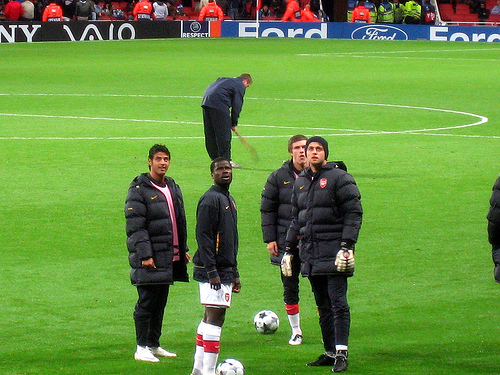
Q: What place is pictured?
A: It is a field.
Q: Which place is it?
A: It is a field.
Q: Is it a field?
A: Yes, it is a field.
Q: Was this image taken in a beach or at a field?
A: It was taken at a field.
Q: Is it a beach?
A: No, it is a field.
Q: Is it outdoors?
A: Yes, it is outdoors.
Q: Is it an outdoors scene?
A: Yes, it is outdoors.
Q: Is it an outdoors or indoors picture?
A: It is outdoors.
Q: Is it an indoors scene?
A: No, it is outdoors.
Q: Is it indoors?
A: No, it is outdoors.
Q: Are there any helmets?
A: No, there are no helmets.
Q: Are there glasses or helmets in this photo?
A: No, there are no helmets or glasses.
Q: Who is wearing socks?
A: The man is wearing socks.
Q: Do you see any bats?
A: Yes, there is a bat.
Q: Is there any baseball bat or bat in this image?
A: Yes, there is a bat.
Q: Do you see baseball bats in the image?
A: No, there are no baseball bats.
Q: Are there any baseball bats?
A: No, there are no baseball bats.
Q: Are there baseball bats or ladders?
A: No, there are no baseball bats or ladders.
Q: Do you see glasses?
A: No, there are no glasses.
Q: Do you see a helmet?
A: No, there are no helmets.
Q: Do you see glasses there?
A: No, there are no glasses.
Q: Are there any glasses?
A: No, there are no glasses.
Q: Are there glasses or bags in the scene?
A: No, there are no glasses or bags.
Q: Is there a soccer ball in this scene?
A: Yes, there is a soccer ball.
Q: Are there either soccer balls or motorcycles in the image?
A: Yes, there is a soccer ball.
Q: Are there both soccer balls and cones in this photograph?
A: No, there is a soccer ball but no cones.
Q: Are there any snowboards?
A: No, there are no snowboards.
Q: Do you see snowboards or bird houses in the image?
A: No, there are no snowboards or bird houses.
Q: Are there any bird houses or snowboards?
A: No, there are no snowboards or bird houses.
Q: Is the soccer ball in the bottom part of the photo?
A: Yes, the soccer ball is in the bottom of the image.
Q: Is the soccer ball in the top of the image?
A: No, the soccer ball is in the bottom of the image.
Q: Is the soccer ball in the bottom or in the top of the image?
A: The soccer ball is in the bottom of the image.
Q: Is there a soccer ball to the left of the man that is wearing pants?
A: Yes, there is a soccer ball to the left of the man.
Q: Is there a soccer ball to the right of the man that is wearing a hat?
A: No, the soccer ball is to the left of the man.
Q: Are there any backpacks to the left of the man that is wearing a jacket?
A: No, there is a soccer ball to the left of the man.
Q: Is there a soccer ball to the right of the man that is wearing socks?
A: Yes, there is a soccer ball to the right of the man.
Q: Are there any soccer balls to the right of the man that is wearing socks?
A: Yes, there is a soccer ball to the right of the man.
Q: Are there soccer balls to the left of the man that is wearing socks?
A: No, the soccer ball is to the right of the man.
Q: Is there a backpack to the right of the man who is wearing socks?
A: No, there is a soccer ball to the right of the man.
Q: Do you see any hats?
A: Yes, there is a hat.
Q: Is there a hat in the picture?
A: Yes, there is a hat.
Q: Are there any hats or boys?
A: Yes, there is a hat.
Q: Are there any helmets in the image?
A: No, there are no helmets.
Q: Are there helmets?
A: No, there are no helmets.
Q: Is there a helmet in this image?
A: No, there are no helmets.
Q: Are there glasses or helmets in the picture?
A: No, there are no helmets or glasses.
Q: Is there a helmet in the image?
A: No, there are no helmets.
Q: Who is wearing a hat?
A: The man is wearing a hat.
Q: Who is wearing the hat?
A: The man is wearing a hat.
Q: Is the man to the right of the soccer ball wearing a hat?
A: Yes, the man is wearing a hat.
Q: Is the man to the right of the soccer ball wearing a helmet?
A: No, the man is wearing a hat.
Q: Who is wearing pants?
A: The man is wearing pants.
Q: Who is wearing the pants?
A: The man is wearing pants.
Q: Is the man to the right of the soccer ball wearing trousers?
A: Yes, the man is wearing trousers.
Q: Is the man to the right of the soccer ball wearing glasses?
A: No, the man is wearing trousers.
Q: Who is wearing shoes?
A: The man is wearing shoes.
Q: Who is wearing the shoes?
A: The man is wearing shoes.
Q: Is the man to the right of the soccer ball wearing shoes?
A: Yes, the man is wearing shoes.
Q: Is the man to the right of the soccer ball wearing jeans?
A: No, the man is wearing shoes.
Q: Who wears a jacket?
A: The man wears a jacket.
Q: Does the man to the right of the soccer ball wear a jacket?
A: Yes, the man wears a jacket.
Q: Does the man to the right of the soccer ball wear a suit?
A: No, the man wears a jacket.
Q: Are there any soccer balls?
A: Yes, there is a soccer ball.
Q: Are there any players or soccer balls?
A: Yes, there is a soccer ball.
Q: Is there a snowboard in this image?
A: No, there are no snowboards.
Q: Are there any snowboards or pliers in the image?
A: No, there are no snowboards or pliers.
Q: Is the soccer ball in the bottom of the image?
A: Yes, the soccer ball is in the bottom of the image.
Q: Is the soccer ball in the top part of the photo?
A: No, the soccer ball is in the bottom of the image.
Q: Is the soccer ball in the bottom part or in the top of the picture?
A: The soccer ball is in the bottom of the image.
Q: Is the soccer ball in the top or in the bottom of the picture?
A: The soccer ball is in the bottom of the image.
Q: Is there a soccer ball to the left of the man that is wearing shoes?
A: Yes, there is a soccer ball to the left of the man.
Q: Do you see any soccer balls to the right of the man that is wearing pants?
A: No, the soccer ball is to the left of the man.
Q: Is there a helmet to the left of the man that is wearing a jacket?
A: No, there is a soccer ball to the left of the man.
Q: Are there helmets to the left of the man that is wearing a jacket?
A: No, there is a soccer ball to the left of the man.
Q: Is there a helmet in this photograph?
A: No, there are no helmets.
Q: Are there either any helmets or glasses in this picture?
A: No, there are no helmets or glasses.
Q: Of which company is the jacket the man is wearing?
A: The jacket is nike.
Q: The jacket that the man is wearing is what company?
A: The jacket is nike.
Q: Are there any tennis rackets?
A: No, there are no tennis rackets.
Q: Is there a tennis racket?
A: No, there are no rackets.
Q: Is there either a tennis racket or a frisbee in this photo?
A: No, there are no rackets or frisbees.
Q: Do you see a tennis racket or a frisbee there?
A: No, there are no rackets or frisbees.